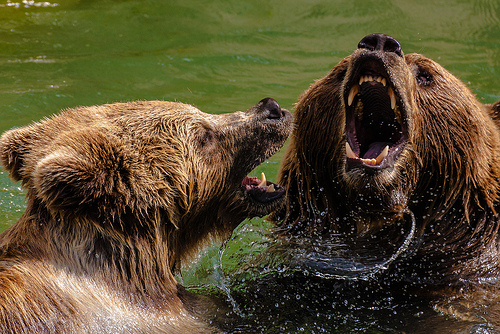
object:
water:
[261, 231, 366, 327]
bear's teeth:
[339, 70, 366, 113]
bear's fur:
[23, 135, 208, 309]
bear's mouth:
[312, 26, 439, 215]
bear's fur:
[68, 146, 198, 307]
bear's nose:
[345, 24, 403, 66]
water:
[205, 250, 310, 330]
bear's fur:
[174, 210, 248, 268]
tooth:
[357, 76, 367, 86]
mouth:
[327, 47, 415, 199]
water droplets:
[192, 242, 301, 329]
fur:
[121, 128, 199, 226]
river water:
[28, 4, 271, 104]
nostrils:
[374, 28, 401, 58]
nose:
[350, 22, 404, 63]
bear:
[210, 30, 493, 334]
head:
[0, 89, 289, 263]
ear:
[31, 143, 110, 206]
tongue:
[361, 128, 389, 165]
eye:
[412, 59, 433, 85]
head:
[267, 31, 496, 246]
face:
[137, 90, 287, 201]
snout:
[219, 99, 290, 151]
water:
[7, 6, 497, 60]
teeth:
[371, 145, 391, 170]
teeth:
[384, 74, 402, 110]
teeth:
[255, 172, 267, 194]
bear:
[0, 97, 300, 332]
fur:
[58, 244, 160, 328]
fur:
[429, 137, 484, 222]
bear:
[229, 33, 498, 332]